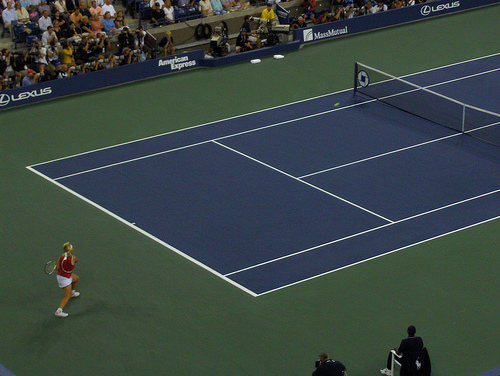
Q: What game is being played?
A: Tennis.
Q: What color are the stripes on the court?
A: White.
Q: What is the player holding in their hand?
A: Tennis racket.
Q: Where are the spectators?
A: In the stands.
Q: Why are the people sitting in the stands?
A: To watch game.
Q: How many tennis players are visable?
A: 1.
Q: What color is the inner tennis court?
A: Blue.